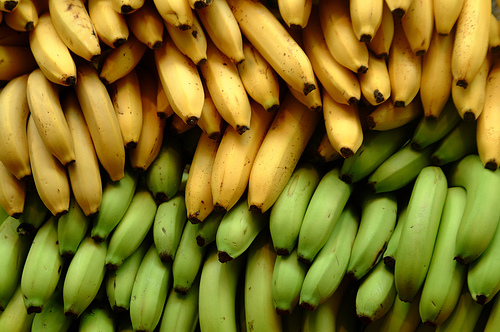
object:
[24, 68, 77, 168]
ripe banana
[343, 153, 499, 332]
bananas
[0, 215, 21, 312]
banana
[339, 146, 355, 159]
brown ends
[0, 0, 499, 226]
yellow bananas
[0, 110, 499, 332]
green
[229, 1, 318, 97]
banana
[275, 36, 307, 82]
brown spots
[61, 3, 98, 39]
brown spot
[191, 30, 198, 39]
brown spot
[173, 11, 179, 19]
brown spot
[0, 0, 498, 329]
bunch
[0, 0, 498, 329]
fruit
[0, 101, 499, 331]
green bananas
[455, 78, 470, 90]
brown end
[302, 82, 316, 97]
brown end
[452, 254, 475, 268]
brown end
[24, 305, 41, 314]
brown end